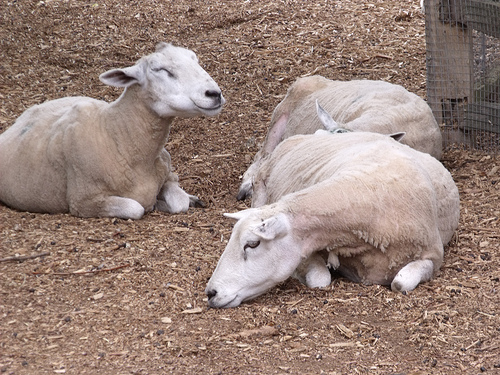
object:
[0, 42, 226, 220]
lamb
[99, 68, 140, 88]
ear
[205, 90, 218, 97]
nose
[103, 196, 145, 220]
leg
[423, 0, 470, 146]
wood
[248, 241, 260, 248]
eye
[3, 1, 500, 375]
photo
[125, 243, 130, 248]
wood chip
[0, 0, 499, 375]
ground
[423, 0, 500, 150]
cage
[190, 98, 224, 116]
mouth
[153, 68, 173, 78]
eye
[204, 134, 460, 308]
lamb